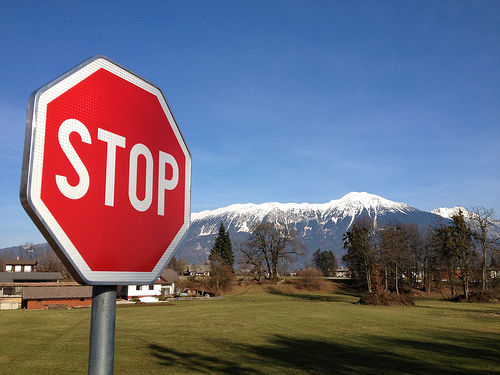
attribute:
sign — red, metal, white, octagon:
[21, 59, 194, 374]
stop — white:
[57, 118, 180, 219]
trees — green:
[207, 209, 498, 305]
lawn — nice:
[7, 294, 499, 374]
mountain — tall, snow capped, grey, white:
[1, 187, 499, 271]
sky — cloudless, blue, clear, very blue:
[1, 2, 500, 191]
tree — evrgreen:
[210, 223, 233, 289]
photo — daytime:
[2, 3, 499, 374]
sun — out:
[1, 275, 345, 360]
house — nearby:
[129, 275, 175, 301]